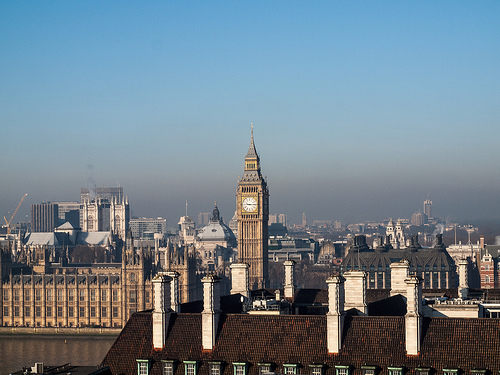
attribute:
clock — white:
[232, 193, 254, 216]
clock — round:
[241, 195, 259, 214]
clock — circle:
[239, 192, 259, 216]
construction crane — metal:
[1, 191, 28, 235]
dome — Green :
[198, 204, 231, 239]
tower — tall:
[228, 133, 275, 284]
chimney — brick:
[342, 271, 369, 312]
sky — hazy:
[1, 5, 495, 259]